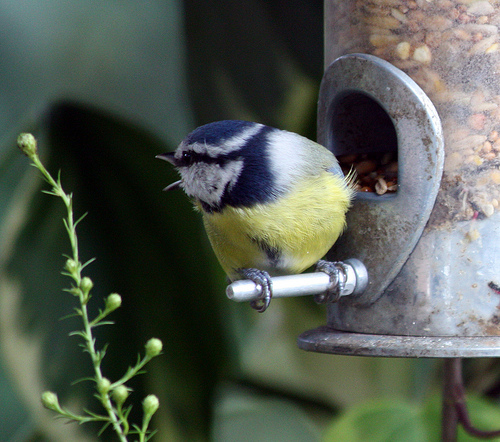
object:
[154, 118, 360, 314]
bird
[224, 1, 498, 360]
feeder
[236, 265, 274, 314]
feet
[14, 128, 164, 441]
plant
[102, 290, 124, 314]
buds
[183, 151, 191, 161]
eye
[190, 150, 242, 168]
line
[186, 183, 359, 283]
part of bird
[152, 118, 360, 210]
half of body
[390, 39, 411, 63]
grains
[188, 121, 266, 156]
stripe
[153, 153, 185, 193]
beak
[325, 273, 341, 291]
nail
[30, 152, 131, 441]
stem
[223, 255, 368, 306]
road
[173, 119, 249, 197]
head